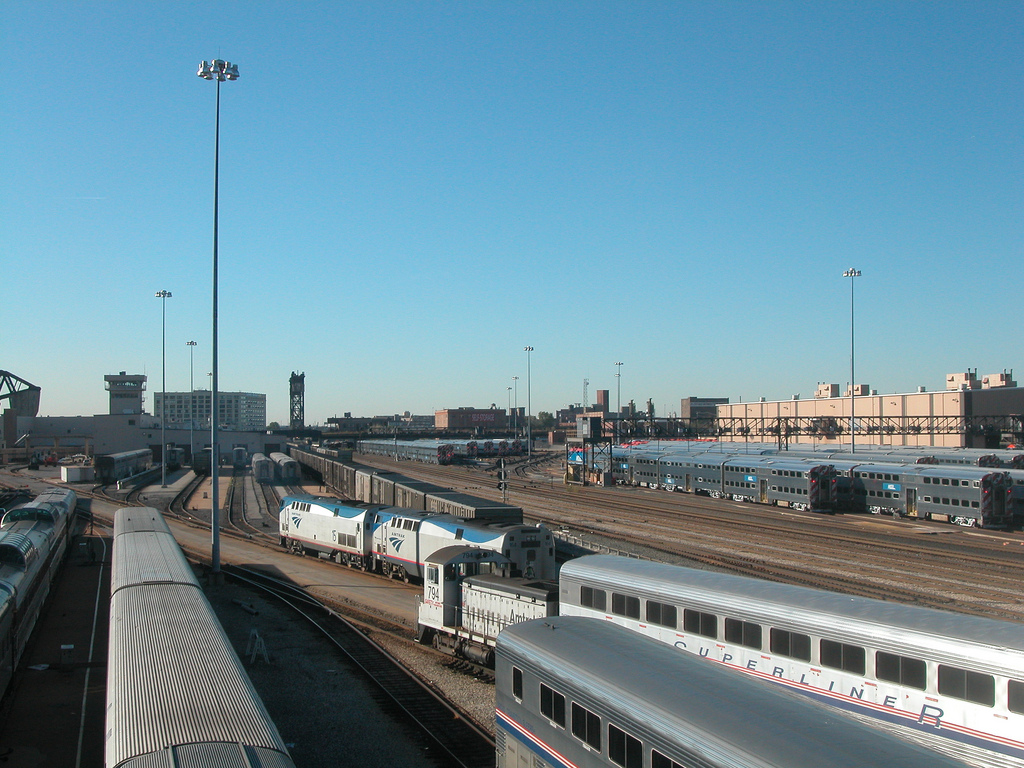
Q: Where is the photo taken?
A: At a train depot.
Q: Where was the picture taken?
A: Near a very large train station in a city.